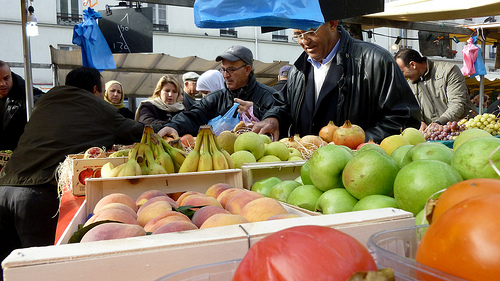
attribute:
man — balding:
[397, 47, 469, 132]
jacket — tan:
[414, 59, 467, 119]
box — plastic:
[371, 178, 498, 280]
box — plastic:
[159, 253, 407, 281]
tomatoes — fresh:
[415, 177, 499, 281]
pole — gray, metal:
[19, 0, 35, 125]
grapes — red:
[424, 115, 462, 145]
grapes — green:
[460, 112, 499, 135]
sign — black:
[102, 10, 156, 54]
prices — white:
[112, 12, 135, 55]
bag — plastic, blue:
[79, 18, 114, 72]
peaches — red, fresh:
[91, 191, 276, 229]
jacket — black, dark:
[278, 47, 412, 128]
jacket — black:
[164, 76, 274, 131]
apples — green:
[260, 142, 500, 212]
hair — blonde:
[157, 75, 183, 87]